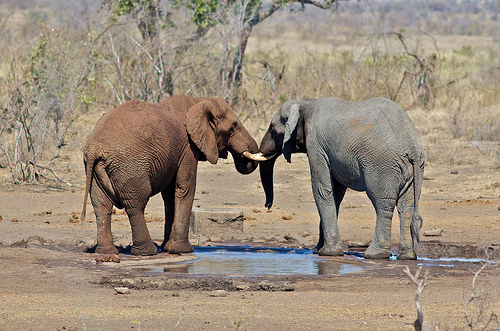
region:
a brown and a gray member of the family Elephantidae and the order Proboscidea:
[37, 37, 481, 298]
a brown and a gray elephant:
[41, 55, 473, 327]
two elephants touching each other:
[37, 47, 462, 287]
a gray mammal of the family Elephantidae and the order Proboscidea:
[256, 75, 451, 290]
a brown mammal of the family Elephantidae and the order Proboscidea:
[60, 70, 257, 265]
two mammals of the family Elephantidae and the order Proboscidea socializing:
[12, 20, 472, 327]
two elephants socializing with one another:
[37, 46, 472, 286]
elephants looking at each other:
[45, 50, 462, 285]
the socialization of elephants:
[60, 65, 467, 282]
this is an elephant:
[83, 94, 263, 261]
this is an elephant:
[257, 95, 442, 254]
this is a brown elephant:
[83, 95, 263, 261]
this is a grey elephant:
[258, 95, 423, 260]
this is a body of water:
[197, 245, 238, 275]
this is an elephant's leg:
[88, 196, 123, 264]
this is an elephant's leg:
[122, 199, 157, 256]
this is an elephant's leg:
[166, 169, 197, 256]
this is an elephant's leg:
[305, 158, 341, 253]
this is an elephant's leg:
[363, 162, 395, 255]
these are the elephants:
[81, 84, 446, 249]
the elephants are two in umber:
[82, 86, 435, 256]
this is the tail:
[401, 160, 431, 222]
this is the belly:
[133, 111, 179, 162]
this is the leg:
[160, 175, 197, 242]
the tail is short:
[72, 156, 99, 221]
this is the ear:
[282, 108, 299, 143]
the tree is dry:
[86, 12, 164, 81]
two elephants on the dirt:
[47, 90, 447, 271]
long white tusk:
[239, 143, 276, 165]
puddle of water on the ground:
[96, 223, 398, 290]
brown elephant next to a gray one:
[67, 88, 434, 278]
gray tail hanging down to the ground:
[406, 153, 426, 257]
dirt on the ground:
[2, 141, 499, 328]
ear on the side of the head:
[277, 105, 304, 162]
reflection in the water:
[163, 264, 190, 273]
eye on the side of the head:
[226, 119, 241, 136]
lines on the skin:
[109, 155, 156, 207]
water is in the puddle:
[172, 250, 332, 285]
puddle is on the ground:
[146, 237, 337, 288]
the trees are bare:
[84, 25, 496, 120]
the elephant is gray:
[278, 104, 443, 270]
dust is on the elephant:
[347, 122, 390, 194]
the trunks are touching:
[234, 122, 286, 199]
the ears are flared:
[182, 95, 218, 172]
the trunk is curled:
[233, 129, 260, 174]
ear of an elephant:
[190, 100, 221, 162]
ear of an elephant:
[275, 106, 300, 162]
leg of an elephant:
[312, 153, 339, 258]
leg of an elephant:
[331, 180, 343, 208]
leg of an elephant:
[372, 189, 392, 257]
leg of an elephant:
[394, 190, 416, 257]